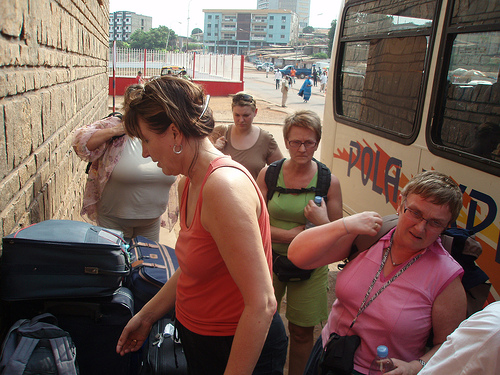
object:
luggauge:
[2, 217, 135, 304]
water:
[368, 357, 395, 374]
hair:
[120, 74, 216, 145]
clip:
[196, 93, 213, 121]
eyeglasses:
[284, 136, 319, 150]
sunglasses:
[399, 194, 452, 233]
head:
[394, 169, 465, 252]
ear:
[168, 121, 187, 147]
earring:
[171, 143, 185, 155]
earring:
[395, 211, 399, 216]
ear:
[392, 191, 404, 214]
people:
[277, 77, 292, 106]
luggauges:
[1, 310, 82, 374]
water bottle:
[368, 345, 397, 374]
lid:
[375, 344, 391, 358]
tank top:
[173, 152, 276, 337]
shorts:
[265, 247, 331, 329]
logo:
[345, 136, 402, 199]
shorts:
[169, 309, 292, 373]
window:
[332, 0, 440, 145]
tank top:
[263, 163, 335, 280]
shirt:
[209, 124, 280, 186]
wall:
[1, 1, 72, 214]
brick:
[18, 155, 38, 188]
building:
[109, 10, 154, 49]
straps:
[263, 156, 283, 197]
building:
[202, 7, 300, 60]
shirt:
[320, 219, 470, 373]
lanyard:
[350, 232, 427, 325]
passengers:
[128, 79, 284, 371]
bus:
[333, 0, 498, 173]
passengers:
[348, 170, 465, 325]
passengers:
[268, 107, 340, 219]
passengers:
[221, 89, 272, 160]